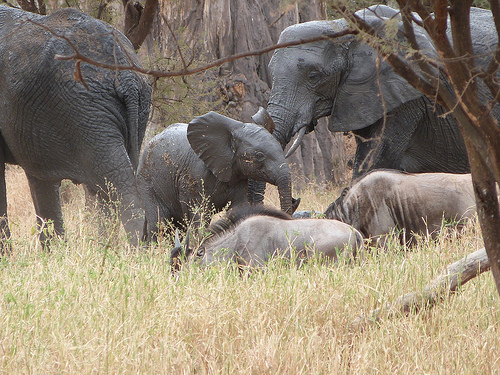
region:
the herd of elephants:
[0, 4, 498, 247]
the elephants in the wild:
[0, 3, 497, 254]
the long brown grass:
[0, 164, 498, 374]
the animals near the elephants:
[170, 167, 479, 276]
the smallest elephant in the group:
[135, 110, 292, 250]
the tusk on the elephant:
[285, 125, 305, 157]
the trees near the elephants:
[0, 0, 498, 332]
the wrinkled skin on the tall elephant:
[1, 5, 151, 256]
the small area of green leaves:
[327, 0, 412, 57]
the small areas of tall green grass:
[0, 177, 497, 374]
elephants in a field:
[72, 79, 493, 372]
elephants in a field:
[57, 45, 419, 238]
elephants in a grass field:
[65, 42, 476, 288]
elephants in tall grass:
[55, 45, 413, 264]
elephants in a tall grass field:
[84, 46, 492, 335]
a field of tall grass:
[111, 197, 461, 374]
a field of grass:
[129, 231, 358, 373]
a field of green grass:
[141, 256, 267, 353]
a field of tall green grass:
[84, 269, 398, 371]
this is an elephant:
[114, 100, 321, 248]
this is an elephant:
[3, 8, 168, 265]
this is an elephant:
[259, 4, 496, 214]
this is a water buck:
[158, 189, 383, 314]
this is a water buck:
[329, 138, 491, 275]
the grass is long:
[44, 242, 111, 346]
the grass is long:
[118, 266, 220, 368]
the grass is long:
[213, 294, 284, 370]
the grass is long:
[293, 298, 327, 361]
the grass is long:
[359, 267, 431, 360]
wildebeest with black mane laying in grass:
[170, 200, 370, 295]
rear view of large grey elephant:
[5, 0, 175, 255]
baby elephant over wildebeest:
[131, 110, 308, 245]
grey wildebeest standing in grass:
[325, 169, 475, 271]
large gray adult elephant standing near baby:
[255, 9, 497, 202]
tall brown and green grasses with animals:
[0, 155, 497, 365]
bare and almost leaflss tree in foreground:
[17, 0, 497, 310]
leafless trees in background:
[5, 0, 499, 165]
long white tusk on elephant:
[277, 128, 313, 165]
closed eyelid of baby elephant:
[247, 146, 267, 164]